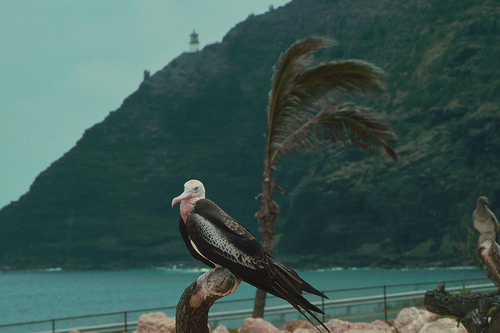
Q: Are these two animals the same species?
A: Yes, all the animals are birds.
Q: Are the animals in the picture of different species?
A: No, all the animals are birds.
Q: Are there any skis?
A: No, there are no skis.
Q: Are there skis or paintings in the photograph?
A: No, there are no skis or paintings.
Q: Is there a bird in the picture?
A: Yes, there is a bird.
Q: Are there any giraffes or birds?
A: Yes, there is a bird.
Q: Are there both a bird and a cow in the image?
A: No, there is a bird but no cows.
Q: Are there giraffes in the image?
A: No, there are no giraffes.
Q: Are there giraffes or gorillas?
A: No, there are no giraffes or gorillas.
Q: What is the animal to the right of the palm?
A: The animal is a bird.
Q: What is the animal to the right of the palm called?
A: The animal is a bird.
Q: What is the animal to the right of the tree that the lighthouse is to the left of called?
A: The animal is a bird.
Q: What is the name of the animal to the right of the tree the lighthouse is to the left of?
A: The animal is a bird.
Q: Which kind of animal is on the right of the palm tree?
A: The animal is a bird.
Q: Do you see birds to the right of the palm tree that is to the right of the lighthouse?
A: Yes, there is a bird to the right of the palm.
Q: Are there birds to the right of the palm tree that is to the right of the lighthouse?
A: Yes, there is a bird to the right of the palm.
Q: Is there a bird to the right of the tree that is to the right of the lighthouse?
A: Yes, there is a bird to the right of the palm.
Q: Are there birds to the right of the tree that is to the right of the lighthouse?
A: Yes, there is a bird to the right of the palm.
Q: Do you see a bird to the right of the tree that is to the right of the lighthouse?
A: Yes, there is a bird to the right of the palm.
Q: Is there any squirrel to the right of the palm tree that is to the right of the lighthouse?
A: No, there is a bird to the right of the palm.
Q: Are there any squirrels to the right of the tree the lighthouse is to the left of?
A: No, there is a bird to the right of the palm.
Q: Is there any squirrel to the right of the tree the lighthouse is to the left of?
A: No, there is a bird to the right of the palm.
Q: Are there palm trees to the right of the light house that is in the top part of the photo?
A: Yes, there is a palm tree to the right of the lighthouse.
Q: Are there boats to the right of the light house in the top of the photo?
A: No, there is a palm tree to the right of the lighthouse.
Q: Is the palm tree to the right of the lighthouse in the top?
A: Yes, the palm tree is to the right of the light house.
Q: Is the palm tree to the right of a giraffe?
A: No, the palm tree is to the right of the light house.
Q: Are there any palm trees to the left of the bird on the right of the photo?
A: Yes, there is a palm tree to the left of the bird.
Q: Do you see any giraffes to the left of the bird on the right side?
A: No, there is a palm tree to the left of the bird.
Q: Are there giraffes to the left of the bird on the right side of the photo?
A: No, there is a palm tree to the left of the bird.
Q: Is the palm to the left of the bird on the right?
A: Yes, the palm is to the left of the bird.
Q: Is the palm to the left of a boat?
A: No, the palm is to the left of the bird.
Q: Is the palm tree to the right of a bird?
A: Yes, the palm tree is to the right of a bird.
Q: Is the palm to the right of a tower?
A: No, the palm is to the right of a bird.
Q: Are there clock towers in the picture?
A: No, there are no clock towers.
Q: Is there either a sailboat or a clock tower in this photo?
A: No, there are no clock towers or sailboats.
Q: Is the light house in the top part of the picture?
A: Yes, the light house is in the top of the image.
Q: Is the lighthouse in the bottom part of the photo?
A: No, the lighthouse is in the top of the image.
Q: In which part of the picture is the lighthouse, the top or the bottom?
A: The lighthouse is in the top of the image.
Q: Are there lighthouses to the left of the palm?
A: Yes, there is a lighthouse to the left of the palm.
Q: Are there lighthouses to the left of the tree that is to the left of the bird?
A: Yes, there is a lighthouse to the left of the palm.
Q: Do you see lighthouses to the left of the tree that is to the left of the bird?
A: Yes, there is a lighthouse to the left of the palm.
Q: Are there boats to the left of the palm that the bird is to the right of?
A: No, there is a lighthouse to the left of the palm tree.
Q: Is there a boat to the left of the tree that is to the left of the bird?
A: No, there is a lighthouse to the left of the palm tree.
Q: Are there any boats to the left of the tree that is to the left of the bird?
A: No, there is a lighthouse to the left of the palm tree.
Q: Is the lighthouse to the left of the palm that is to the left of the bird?
A: Yes, the lighthouse is to the left of the palm tree.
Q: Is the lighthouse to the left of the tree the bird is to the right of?
A: Yes, the lighthouse is to the left of the palm tree.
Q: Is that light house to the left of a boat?
A: No, the light house is to the left of the palm tree.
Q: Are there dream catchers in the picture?
A: No, there are no dream catchers.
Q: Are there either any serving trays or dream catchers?
A: No, there are no dream catchers or serving trays.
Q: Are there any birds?
A: Yes, there is a bird.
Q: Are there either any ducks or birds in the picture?
A: Yes, there is a bird.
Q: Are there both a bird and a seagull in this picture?
A: No, there is a bird but no seagulls.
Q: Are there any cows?
A: No, there are no cows.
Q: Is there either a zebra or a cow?
A: No, there are no cows or zebras.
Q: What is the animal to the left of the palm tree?
A: The animal is a bird.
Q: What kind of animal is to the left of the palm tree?
A: The animal is a bird.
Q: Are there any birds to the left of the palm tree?
A: Yes, there is a bird to the left of the palm tree.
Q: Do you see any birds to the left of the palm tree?
A: Yes, there is a bird to the left of the palm tree.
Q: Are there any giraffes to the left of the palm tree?
A: No, there is a bird to the left of the palm tree.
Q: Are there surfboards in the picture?
A: No, there are no surfboards.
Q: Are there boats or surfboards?
A: No, there are no surfboards or boats.